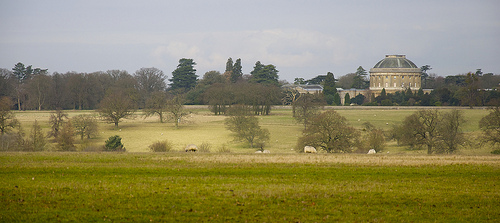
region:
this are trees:
[90, 72, 412, 208]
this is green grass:
[45, 170, 235, 220]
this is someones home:
[303, 55, 437, 90]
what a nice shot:
[35, 26, 447, 186]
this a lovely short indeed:
[24, 29, 464, 201]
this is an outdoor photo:
[50, 18, 285, 38]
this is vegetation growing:
[15, 62, 297, 96]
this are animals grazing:
[278, 138, 350, 162]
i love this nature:
[42, 28, 436, 205]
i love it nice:
[74, 35, 296, 206]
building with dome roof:
[361, 48, 433, 99]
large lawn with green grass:
[2, 150, 499, 220]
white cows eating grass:
[295, 136, 393, 166]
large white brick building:
[267, 46, 450, 112]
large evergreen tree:
[171, 55, 208, 108]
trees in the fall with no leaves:
[1, 60, 135, 116]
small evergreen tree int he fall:
[98, 127, 130, 157]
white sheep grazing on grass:
[175, 140, 203, 167]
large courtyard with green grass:
[33, 76, 495, 143]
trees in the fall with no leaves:
[1, 91, 107, 168]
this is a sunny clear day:
[0, 0, 498, 221]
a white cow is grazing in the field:
[304, 143, 316, 153]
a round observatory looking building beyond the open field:
[369, 53, 423, 98]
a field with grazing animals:
[0, 109, 499, 221]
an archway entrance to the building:
[339, 87, 356, 104]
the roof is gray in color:
[369, 55, 421, 69]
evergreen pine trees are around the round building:
[320, 70, 337, 102]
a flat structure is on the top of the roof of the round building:
[385, 53, 405, 58]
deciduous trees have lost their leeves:
[97, 83, 134, 126]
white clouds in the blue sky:
[0, 0, 498, 86]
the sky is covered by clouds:
[208, 8, 268, 58]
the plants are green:
[251, 196, 287, 221]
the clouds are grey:
[233, 10, 285, 53]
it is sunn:
[13, 12, 424, 217]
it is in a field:
[8, 10, 458, 212]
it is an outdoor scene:
[2, 22, 457, 214]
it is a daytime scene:
[13, 10, 479, 210]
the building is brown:
[368, 32, 458, 127]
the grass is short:
[202, 175, 290, 207]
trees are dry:
[299, 105, 479, 166]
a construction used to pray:
[365, 47, 426, 112]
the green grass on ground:
[40, 156, 275, 221]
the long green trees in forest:
[12, 60, 252, 111]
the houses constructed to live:
[288, 76, 339, 106]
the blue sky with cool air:
[37, 12, 321, 67]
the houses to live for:
[288, 71, 348, 111]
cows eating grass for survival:
[296, 140, 321, 160]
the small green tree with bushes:
[103, 127, 128, 152]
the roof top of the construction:
[361, 45, 431, 80]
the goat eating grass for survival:
[182, 141, 202, 163]